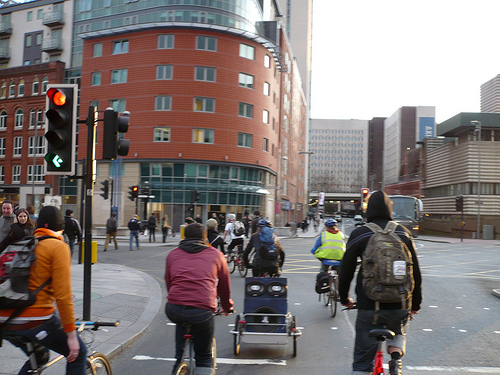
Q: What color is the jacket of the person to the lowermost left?
A: Orange.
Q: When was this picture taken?
A: Day time.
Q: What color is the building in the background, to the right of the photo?
A: Red.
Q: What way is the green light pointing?
A: Left.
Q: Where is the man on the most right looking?
A: Forward.